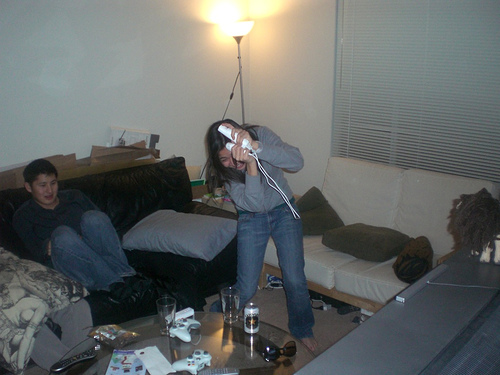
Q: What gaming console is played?
A: Wii.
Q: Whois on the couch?
A: The boy.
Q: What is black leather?
A: Couch.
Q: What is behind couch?
A: Flattened boxes.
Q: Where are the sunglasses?
A: On table.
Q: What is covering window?
A: Blinds.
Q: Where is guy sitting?
A: On the couch.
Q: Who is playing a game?
A: Girl.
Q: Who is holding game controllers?
A: The girl.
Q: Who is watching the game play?
A: The boy.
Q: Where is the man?
A: On the couch.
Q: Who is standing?
A: The girl.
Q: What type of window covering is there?
A: Blinds.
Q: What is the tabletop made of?
A: Glass.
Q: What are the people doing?
A: Playing a game.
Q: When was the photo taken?
A: Nighttime.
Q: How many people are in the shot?
A: 2.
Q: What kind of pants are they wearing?
A: Jeans.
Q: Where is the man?
A: On the couch.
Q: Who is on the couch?
A: The man.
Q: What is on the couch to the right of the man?
A: A pillow.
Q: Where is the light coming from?
A: A lamp.